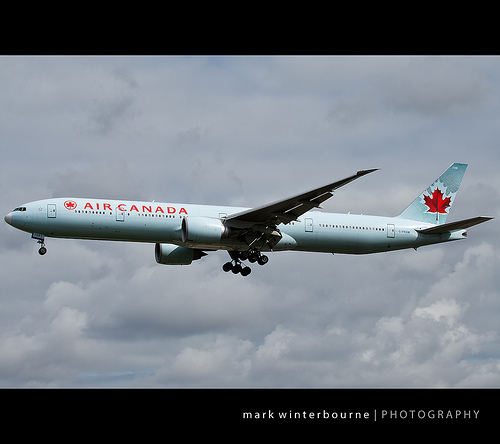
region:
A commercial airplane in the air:
[0, 145, 496, 285]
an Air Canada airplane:
[3, 155, 496, 279]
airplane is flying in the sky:
[12, 154, 492, 271]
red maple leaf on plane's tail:
[416, 173, 461, 222]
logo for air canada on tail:
[419, 180, 457, 218]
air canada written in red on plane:
[59, 190, 189, 222]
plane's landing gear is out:
[208, 242, 275, 283]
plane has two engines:
[151, 217, 300, 275]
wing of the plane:
[213, 165, 384, 233]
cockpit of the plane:
[0, 198, 42, 233]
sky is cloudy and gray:
[3, 54, 498, 386]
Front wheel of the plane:
[34, 244, 54, 257]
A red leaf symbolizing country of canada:
[420, 182, 455, 222]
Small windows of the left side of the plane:
[316, 222, 387, 233]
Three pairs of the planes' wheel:
[218, 250, 275, 280]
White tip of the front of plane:
[2, 207, 26, 232]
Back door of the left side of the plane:
[383, 222, 400, 240]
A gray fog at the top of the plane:
[70, 68, 186, 138]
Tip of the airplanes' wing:
[350, 157, 377, 179]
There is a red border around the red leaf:
[57, 197, 82, 211]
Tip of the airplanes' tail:
[457, 225, 479, 243]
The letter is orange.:
[81, 198, 95, 215]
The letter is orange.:
[93, 197, 103, 213]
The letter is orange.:
[101, 199, 113, 214]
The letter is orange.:
[116, 197, 129, 217]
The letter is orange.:
[126, 200, 142, 218]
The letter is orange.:
[138, 202, 156, 218]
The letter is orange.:
[163, 198, 178, 218]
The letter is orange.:
[176, 203, 191, 218]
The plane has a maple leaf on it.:
[1, 142, 495, 290]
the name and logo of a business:
[58, 198, 189, 216]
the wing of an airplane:
[216, 163, 380, 223]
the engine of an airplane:
[180, 218, 237, 245]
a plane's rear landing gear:
[213, 242, 270, 278]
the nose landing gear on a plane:
[26, 230, 51, 260]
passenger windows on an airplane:
[135, 210, 180, 220]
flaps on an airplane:
[280, 191, 333, 226]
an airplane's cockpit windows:
[10, 203, 30, 213]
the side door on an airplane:
[384, 220, 395, 238]